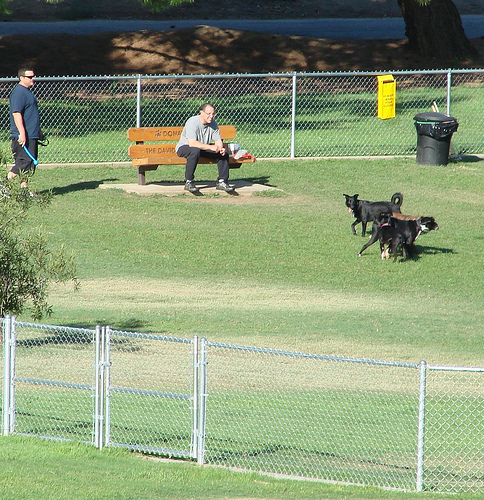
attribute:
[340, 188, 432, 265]
dogs — playing, standing, next to each other, pack, black, four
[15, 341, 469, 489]
fence — chain-link, chain link, metal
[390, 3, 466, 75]
tree — trunk, large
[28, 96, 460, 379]
grass — green, patch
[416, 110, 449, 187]
trash can — black, plastic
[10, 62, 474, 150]
fence — back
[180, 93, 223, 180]
man — sitting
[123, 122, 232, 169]
bench — wooden, wood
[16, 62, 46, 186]
man — standing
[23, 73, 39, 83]
sunglasses — black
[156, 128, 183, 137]
letters — engraved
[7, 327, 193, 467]
gate — chain link, chain-link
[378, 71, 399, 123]
container — yellow, hanging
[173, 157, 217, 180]
pants — black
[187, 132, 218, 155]
shirt — gray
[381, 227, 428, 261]
dog — black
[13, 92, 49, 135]
shirt — blue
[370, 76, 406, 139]
bin — yellow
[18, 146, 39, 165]
ball tosser — blue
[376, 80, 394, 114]
box — yellow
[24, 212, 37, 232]
leaves — green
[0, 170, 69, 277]
tree — smaller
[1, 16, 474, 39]
sidewalk — concrete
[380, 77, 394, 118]
bag dispenser — yellow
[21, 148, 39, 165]
stick — blue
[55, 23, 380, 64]
dirt — mound